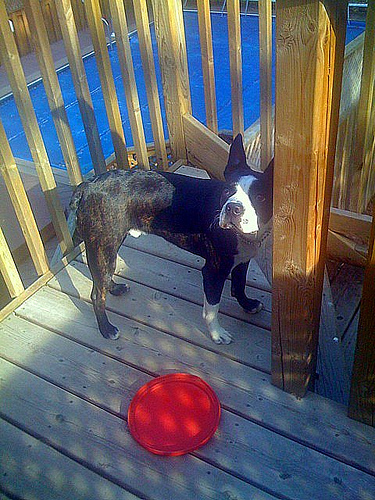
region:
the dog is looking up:
[28, 144, 292, 335]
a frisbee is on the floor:
[73, 340, 258, 483]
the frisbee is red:
[89, 351, 253, 479]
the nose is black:
[214, 193, 251, 228]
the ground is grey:
[11, 325, 257, 484]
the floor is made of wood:
[10, 316, 132, 483]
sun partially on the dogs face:
[210, 195, 263, 238]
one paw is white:
[187, 297, 245, 353]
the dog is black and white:
[53, 140, 264, 373]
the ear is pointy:
[215, 120, 264, 183]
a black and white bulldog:
[68, 134, 273, 344]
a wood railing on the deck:
[1, 1, 212, 168]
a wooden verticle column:
[268, 1, 334, 396]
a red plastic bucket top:
[125, 370, 222, 457]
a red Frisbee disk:
[126, 371, 220, 456]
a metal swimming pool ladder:
[98, 14, 115, 54]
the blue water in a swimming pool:
[241, 14, 258, 122]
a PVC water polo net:
[345, 2, 366, 26]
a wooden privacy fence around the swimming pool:
[7, 2, 33, 59]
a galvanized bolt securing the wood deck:
[332, 336, 339, 342]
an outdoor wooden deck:
[0, 0, 374, 498]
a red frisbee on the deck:
[126, 372, 220, 456]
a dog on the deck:
[68, 133, 274, 344]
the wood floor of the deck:
[0, 164, 373, 498]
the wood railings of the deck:
[0, 0, 374, 428]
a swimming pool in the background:
[0, 9, 366, 175]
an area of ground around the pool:
[0, 0, 367, 310]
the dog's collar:
[235, 230, 270, 249]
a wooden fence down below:
[242, 30, 365, 170]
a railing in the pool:
[100, 17, 112, 50]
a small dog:
[52, 137, 322, 380]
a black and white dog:
[65, 147, 354, 382]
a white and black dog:
[86, 137, 331, 343]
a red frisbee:
[114, 371, 261, 475]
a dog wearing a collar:
[72, 157, 334, 356]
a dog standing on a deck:
[72, 133, 350, 359]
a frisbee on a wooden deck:
[55, 366, 261, 498]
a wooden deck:
[89, 17, 363, 172]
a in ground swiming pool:
[0, 0, 369, 199]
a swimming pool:
[7, 2, 372, 215]